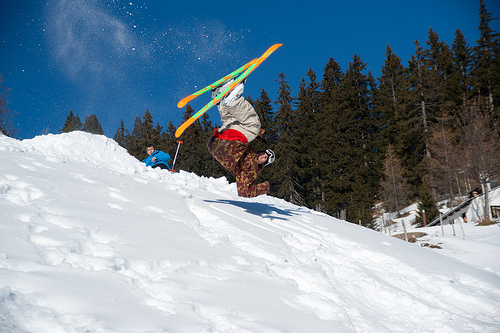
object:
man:
[142, 143, 173, 171]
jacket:
[141, 150, 173, 168]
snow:
[0, 130, 495, 332]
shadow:
[203, 199, 299, 222]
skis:
[173, 43, 284, 140]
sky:
[0, 0, 499, 139]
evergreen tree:
[268, 70, 305, 206]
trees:
[313, 54, 381, 224]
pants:
[213, 89, 260, 141]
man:
[207, 74, 277, 198]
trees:
[61, 110, 84, 133]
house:
[425, 186, 499, 227]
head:
[253, 148, 274, 166]